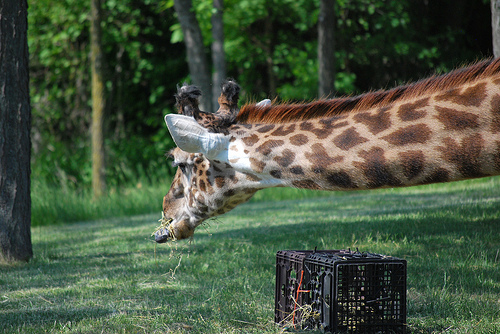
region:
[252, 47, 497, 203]
A giraffe's spotted neck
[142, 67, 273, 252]
A giraffe's spotted head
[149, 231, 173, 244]
A giraffe's black tongue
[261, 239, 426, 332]
A black plastic crate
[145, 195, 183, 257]
Hay in a giraffe's mouth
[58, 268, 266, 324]
A green grassy area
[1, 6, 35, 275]
A gray tree trunk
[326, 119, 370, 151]
A brown spot on a giraffe's neck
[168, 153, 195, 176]
A giraffe's left eye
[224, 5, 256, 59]
Green tree leaves in the background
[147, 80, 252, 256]
head of a giraffe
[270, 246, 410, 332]
a black plastic basket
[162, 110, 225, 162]
back of a giraffe's ear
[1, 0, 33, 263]
trunk of a tree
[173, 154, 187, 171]
eye of a giraffe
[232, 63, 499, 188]
neck of a giraffe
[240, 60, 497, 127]
a giraffe's mane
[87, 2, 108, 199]
trunk of a tree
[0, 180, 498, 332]
a field of grass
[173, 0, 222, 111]
tree in the distance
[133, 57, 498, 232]
giraffe with its head extended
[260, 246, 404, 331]
black crate with straw inside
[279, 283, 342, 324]
pieces of straw sticking out of a crate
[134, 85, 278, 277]
a giraffe eating straw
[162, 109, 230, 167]
long white ear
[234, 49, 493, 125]
short brown mane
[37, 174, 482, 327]
trimmed lawn in the shade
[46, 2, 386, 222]
tree trunks and leaves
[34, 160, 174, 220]
tall grass next to trimmed grass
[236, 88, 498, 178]
thick giraffe neck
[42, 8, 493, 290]
a giraffes head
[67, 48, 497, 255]
a giraffe's neck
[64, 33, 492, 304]
a giraffe that is outside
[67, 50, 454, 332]
a giraffe in a field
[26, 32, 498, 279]
a giraffe that is eatting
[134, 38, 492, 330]
a giraffe eating grass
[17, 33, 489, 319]
a field with a giraffe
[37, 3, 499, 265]
a green field with an eatting giraffe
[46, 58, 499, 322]
an area with a giraffe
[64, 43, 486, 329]
an area with an eating giraffe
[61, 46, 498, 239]
This is a giraffe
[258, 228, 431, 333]
This is a basket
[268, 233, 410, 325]
This is a black basket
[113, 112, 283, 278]
The giraffe is grazing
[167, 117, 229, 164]
The giraffes ears are white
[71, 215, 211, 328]
This ground is made of grass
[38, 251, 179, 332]
This grass is green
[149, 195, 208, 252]
The giraffe is eating grass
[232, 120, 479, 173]
The giraffe is brown and yellow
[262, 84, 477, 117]
The giraffes mane is orange